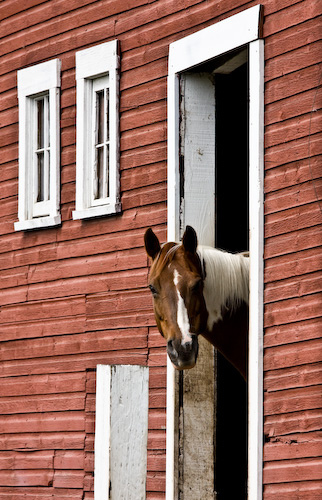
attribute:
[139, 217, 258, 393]
horse — brown, white, looking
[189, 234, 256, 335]
fur — white, brown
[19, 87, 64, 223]
window — open, white, closed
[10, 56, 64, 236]
frame — white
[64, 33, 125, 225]
frame — white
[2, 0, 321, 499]
wall — brown, wooden, red, wood, decayed wood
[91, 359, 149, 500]
pole — white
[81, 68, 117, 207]
window — white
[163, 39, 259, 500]
opening — white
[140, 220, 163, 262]
ear — brown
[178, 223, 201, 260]
ear — brown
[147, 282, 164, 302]
eye — black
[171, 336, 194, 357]
nose — black, large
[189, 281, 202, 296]
eye — black